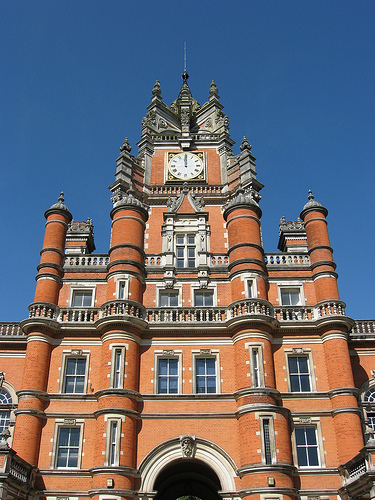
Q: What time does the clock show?
A: 12:00.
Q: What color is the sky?
A: Blue.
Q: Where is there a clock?
A: On the building.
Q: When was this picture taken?
A: Daytime.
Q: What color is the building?
A: Orange.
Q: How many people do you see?
A: 0.